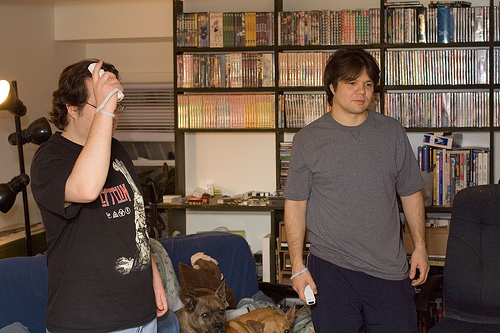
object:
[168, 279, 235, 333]
dog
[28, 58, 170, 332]
man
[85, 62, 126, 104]
controller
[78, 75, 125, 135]
face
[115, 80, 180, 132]
blinds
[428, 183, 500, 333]
chair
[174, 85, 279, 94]
space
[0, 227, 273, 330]
sofa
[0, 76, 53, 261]
fixtures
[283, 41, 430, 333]
man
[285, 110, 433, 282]
t-shirt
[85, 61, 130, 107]
wii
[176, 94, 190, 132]
neatly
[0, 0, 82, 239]
wall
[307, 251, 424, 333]
sweats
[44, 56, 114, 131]
hair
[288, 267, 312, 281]
strap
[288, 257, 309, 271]
wrist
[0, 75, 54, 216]
three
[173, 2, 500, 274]
bookcase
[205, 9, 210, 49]
rows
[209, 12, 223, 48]
books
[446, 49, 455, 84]
no subject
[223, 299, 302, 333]
dog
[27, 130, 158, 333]
t shirt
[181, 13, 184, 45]
object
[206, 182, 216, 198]
object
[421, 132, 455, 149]
object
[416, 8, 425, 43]
object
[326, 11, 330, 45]
object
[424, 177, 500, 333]
couch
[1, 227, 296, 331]
couch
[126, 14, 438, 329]
inside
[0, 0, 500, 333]
house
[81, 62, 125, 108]
game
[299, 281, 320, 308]
wii controller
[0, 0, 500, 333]
room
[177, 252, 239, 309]
clothes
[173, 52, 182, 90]
dvds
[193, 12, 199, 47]
dvds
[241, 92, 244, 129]
dvds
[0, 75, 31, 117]
lamp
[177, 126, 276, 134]
shelf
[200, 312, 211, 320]
eyes